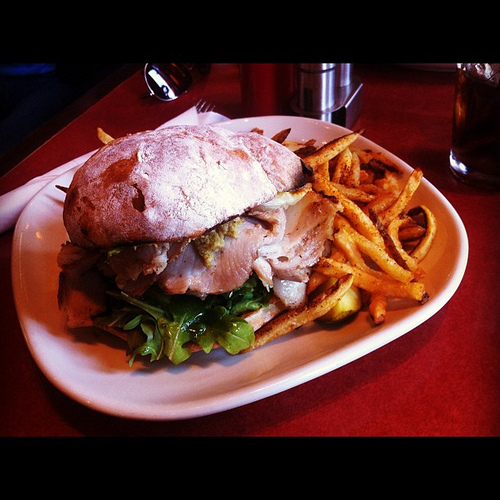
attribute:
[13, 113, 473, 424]
plate — white, square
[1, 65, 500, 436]
table — wooden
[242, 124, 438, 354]
french fries — seasoned, golden brown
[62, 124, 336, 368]
sandwich — full, big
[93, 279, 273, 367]
lettuce — green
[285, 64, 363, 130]
salt and pepper shak — silver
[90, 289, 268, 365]
greens — leafy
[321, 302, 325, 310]
speck — black